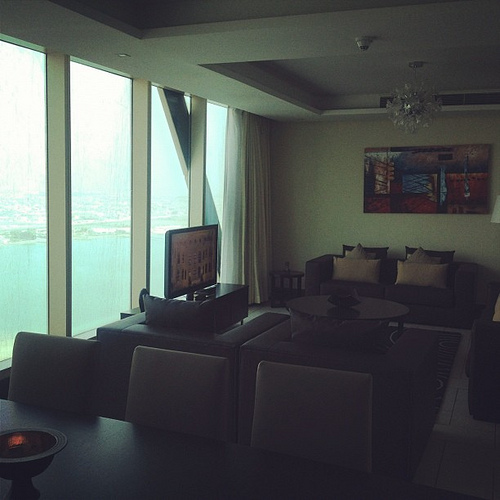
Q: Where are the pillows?
A: On the couch.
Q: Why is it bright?
A: During day.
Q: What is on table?
A: Bowl.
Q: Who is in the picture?
A: No one.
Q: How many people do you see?
A: None.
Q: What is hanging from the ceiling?
A: Light.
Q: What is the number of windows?
A: 4.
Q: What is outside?
A: Water.